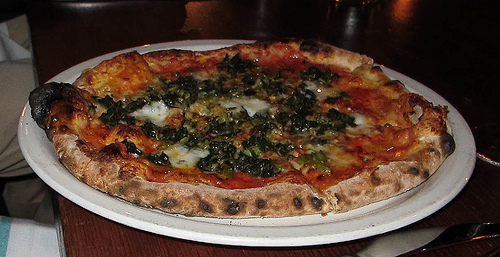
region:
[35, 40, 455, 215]
A cooked pizza on a dish.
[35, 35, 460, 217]
Vegetable pizza with cheese.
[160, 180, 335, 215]
Crust of pizza.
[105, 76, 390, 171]
Pizza tomato sauce with cheese.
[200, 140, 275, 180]
Spinach on a pizza.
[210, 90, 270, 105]
Melted white cheese.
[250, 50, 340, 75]
Pizza tomato sauce.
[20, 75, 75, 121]
Burned crust of pizza.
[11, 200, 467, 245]
A white round dish.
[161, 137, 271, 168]
Melted cheese with spinach.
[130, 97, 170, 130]
white melted cheese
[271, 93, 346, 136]
green colored pizza topping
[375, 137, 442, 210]
section of pizza crust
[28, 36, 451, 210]
fresh baked pizza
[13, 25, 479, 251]
pizza sitting on a plate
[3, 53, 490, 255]
pizza on a plate on a table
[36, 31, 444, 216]
cheesy greasy pizza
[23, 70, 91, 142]
burnt section of crust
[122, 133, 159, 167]
red pizza sauce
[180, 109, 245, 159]
spinach pizza topping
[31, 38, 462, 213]
a well done pizza pie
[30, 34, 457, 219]
a pizza with vegetables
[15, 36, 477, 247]
a pizza on a white plate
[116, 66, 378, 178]
melted green vegetables on pizza crust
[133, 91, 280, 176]
white pieces of melted cheese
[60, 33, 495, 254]
wooden table with pizza on top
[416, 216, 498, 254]
a metal spoon laying on table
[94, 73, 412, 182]
tomato sauce on pizza pie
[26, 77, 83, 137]
burned pizza crust on edge of pizza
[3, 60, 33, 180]
a beige fabric on the distance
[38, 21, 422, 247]
spinach pizza on a white plate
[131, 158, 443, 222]
very brown crust on pizza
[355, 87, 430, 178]
tomato sauce on a pizza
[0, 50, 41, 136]
khaki pants at the table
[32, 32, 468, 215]
pizza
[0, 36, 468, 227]
white plate on the table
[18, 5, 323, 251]
pizza is sitting on a brown table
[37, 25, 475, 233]
full plate of pizza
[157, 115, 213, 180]
cheese on the spinach pizza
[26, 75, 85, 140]
burnt crust on the spinach and cheese pizza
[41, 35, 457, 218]
pizza with cheese, tomatoes and greens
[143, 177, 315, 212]
pizza crust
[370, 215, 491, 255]
knife on a table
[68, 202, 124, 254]
table where people are eating pizza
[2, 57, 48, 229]
a person's leg sitting at a table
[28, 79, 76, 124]
bit of burned pizza crust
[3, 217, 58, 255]
napkin on person's leg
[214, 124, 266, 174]
green topping on pizza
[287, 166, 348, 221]
slice park on pizza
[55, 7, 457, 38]
dinner table top